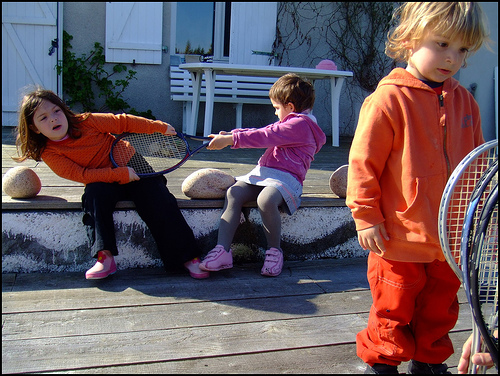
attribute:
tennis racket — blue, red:
[110, 125, 210, 177]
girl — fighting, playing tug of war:
[203, 75, 324, 274]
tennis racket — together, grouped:
[435, 138, 499, 285]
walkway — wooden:
[1, 126, 496, 376]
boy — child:
[350, 0, 497, 375]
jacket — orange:
[344, 74, 494, 263]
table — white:
[169, 62, 351, 149]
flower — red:
[95, 248, 108, 267]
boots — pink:
[198, 240, 300, 283]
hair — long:
[379, 6, 494, 54]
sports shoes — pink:
[71, 241, 210, 291]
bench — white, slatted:
[181, 61, 354, 143]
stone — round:
[180, 170, 244, 204]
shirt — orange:
[37, 108, 166, 191]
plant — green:
[47, 33, 169, 131]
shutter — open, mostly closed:
[101, 3, 177, 72]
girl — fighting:
[24, 93, 206, 278]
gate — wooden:
[1, 0, 62, 126]